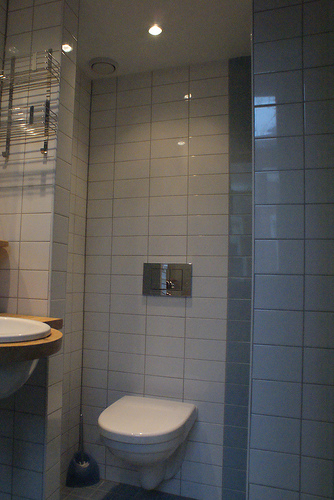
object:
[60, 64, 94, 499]
wall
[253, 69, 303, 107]
tile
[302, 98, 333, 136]
tile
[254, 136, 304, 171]
tile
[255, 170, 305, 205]
tile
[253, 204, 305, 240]
tile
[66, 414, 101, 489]
brush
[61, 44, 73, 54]
lights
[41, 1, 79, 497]
wall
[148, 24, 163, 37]
light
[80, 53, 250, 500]
wall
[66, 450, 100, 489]
holder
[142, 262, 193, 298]
window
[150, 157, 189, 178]
tile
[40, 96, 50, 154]
metal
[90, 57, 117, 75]
detector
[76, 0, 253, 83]
ceiling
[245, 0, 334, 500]
wall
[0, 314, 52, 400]
sink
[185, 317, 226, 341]
tile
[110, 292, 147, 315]
tile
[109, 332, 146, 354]
tile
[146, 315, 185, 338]
tile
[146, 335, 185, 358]
tile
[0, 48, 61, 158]
rack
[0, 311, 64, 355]
counter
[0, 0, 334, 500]
bathroom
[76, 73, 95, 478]
corner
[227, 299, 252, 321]
tile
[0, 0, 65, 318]
wall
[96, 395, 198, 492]
toilet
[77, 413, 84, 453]
handle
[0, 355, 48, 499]
wall